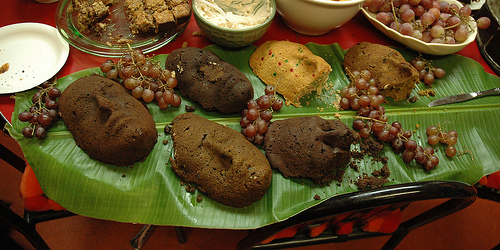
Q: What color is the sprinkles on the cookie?
A: Red and green.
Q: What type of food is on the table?
A: Desserts.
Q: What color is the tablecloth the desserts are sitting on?
A: Green.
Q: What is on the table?
A: Grapes.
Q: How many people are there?
A: None.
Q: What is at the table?
A: Chair.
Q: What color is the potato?
A: Brown.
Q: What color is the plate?
A: White.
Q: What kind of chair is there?
A: Metal.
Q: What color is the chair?
A: Black.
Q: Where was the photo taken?
A: Indoors somewhere.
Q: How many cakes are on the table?
A: 6.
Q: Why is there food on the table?
A: For a brunch.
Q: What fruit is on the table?
A: Grapes.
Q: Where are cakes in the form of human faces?
A: On a green leaf.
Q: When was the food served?
A: Mid morning.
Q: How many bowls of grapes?
A: One.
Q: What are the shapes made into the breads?
A: Faces.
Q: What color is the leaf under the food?
A: Green.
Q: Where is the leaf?
A: Under the food.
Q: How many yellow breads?
A: One.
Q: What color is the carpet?
A: Red.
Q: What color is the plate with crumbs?
A: White.